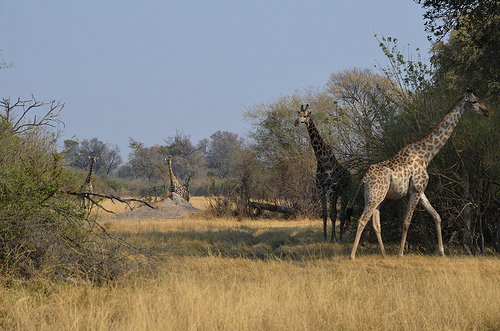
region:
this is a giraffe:
[324, 104, 446, 234]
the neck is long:
[392, 74, 479, 204]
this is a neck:
[393, 78, 472, 226]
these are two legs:
[310, 214, 487, 259]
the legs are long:
[331, 211, 459, 268]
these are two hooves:
[335, 246, 416, 262]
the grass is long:
[212, 262, 247, 318]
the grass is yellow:
[190, 261, 230, 312]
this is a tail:
[337, 194, 371, 245]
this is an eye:
[446, 76, 482, 106]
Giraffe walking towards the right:
[352, 82, 489, 264]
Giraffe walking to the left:
[291, 90, 356, 265]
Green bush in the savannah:
[0, 95, 117, 282]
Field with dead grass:
[0, 192, 497, 328]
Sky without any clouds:
[2, 1, 446, 156]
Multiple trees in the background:
[56, 116, 312, 196]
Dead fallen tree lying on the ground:
[245, 190, 305, 215]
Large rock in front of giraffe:
[105, 188, 205, 220]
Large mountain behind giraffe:
[405, 0, 496, 248]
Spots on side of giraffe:
[389, 167, 420, 184]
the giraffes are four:
[73, 85, 498, 252]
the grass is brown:
[227, 260, 350, 324]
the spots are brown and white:
[386, 150, 421, 181]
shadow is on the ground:
[197, 213, 291, 270]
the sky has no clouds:
[56, 20, 293, 124]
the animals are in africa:
[3, 5, 484, 327]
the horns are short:
[298, 105, 315, 111]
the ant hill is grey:
[151, 185, 213, 225]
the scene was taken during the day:
[5, 8, 499, 328]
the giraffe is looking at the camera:
[298, 102, 322, 134]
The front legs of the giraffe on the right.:
[400, 185, 443, 261]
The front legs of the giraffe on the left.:
[318, 190, 338, 245]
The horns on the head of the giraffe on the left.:
[299, 103, 309, 107]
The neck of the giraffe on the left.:
[305, 123, 325, 153]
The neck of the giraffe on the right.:
[425, 98, 462, 157]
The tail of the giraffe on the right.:
[342, 172, 362, 218]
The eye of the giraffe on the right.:
[471, 98, 476, 105]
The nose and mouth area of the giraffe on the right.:
[479, 107, 491, 117]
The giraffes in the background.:
[75, 144, 201, 208]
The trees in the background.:
[31, 100, 300, 200]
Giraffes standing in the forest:
[60, 0, 492, 325]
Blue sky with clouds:
[116, 22, 266, 89]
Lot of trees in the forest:
[71, 23, 482, 167]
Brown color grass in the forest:
[201, 257, 356, 312]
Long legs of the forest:
[359, 212, 447, 256]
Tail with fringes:
[342, 193, 357, 225]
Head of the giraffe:
[451, 78, 492, 120]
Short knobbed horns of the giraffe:
[297, 100, 313, 109]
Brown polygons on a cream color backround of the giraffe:
[403, 148, 425, 180]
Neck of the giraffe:
[431, 118, 456, 148]